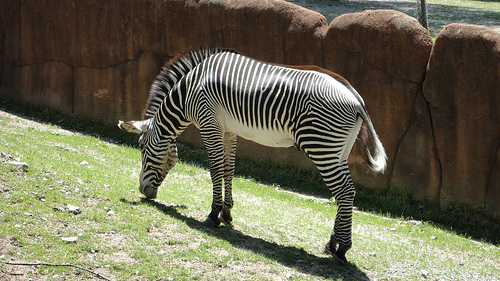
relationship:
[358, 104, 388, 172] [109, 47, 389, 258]
tail of zebra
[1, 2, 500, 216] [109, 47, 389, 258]
wall behind zebra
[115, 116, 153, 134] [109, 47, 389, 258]
ear of zebra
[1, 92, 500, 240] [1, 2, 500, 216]
shadow of wall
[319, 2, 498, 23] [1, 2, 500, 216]
fence behind wall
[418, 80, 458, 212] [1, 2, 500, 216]
crack on wall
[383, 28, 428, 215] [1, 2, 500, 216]
crack on wall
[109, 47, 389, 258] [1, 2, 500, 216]
zebra in enclosure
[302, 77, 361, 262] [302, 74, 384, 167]
stripes on back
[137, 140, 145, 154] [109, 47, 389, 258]
eye of zebra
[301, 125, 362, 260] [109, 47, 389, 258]
back leg of zebra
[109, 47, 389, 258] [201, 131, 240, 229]
zebra have front legs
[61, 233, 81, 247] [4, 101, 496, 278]
rock on ground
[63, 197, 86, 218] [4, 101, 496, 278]
rock on ground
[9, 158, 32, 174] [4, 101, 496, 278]
rock on ground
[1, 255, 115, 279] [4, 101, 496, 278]
stick on ground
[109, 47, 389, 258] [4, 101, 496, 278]
zebra on grass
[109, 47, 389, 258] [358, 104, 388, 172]
zebra has a tail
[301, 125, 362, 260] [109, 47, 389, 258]
hind leg of zebra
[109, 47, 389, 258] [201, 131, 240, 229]
zebra has front legs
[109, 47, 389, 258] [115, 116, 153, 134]
zebra has ear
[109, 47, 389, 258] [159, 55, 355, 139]
zebra has stripes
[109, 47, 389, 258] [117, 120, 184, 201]
zebra has head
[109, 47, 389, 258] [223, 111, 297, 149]
zebra has a belly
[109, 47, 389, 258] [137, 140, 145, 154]
zebra has an eye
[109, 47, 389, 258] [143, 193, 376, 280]
zebra has shadow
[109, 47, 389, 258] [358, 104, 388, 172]
zebra has tail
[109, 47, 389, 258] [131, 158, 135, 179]
zebra looking downward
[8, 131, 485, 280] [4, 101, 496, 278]
grass on ground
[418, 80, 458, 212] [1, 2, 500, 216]
crack in wall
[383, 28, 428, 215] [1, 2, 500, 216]
crack in wall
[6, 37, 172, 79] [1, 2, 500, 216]
crack in wall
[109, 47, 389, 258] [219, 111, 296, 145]
zebra has belly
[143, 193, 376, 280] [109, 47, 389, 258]
shadow of zebra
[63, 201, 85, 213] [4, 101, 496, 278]
stone on ground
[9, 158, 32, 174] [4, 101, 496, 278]
stone on ground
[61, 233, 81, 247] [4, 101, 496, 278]
stone on ground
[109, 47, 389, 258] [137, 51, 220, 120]
zebra has mane